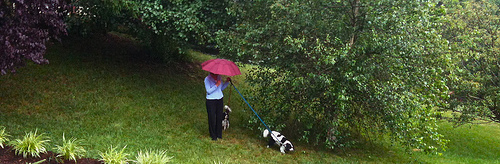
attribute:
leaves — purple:
[30, 46, 53, 63]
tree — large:
[237, 1, 473, 154]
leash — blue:
[225, 80, 277, 120]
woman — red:
[204, 72, 229, 140]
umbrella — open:
[202, 57, 240, 75]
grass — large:
[1, 32, 498, 162]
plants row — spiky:
[2, 122, 182, 162]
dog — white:
[257, 125, 299, 157]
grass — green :
[11, 44, 206, 156]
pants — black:
[205, 100, 230, 138]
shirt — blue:
[202, 74, 232, 101]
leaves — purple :
[279, 31, 435, 118]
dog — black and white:
[258, 123, 295, 153]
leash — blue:
[224, 81, 271, 128]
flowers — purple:
[0, 24, 62, 93]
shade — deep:
[78, 33, 188, 111]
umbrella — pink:
[199, 52, 244, 79]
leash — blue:
[229, 82, 284, 143]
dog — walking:
[261, 127, 294, 154]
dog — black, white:
[259, 122, 297, 151]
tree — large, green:
[236, 2, 458, 162]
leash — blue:
[230, 81, 271, 129]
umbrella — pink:
[197, 54, 242, 85]